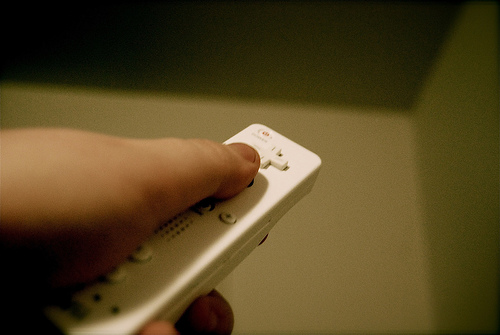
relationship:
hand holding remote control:
[1, 111, 242, 333] [60, 113, 333, 334]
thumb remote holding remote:
[186, 107, 338, 189] [31, 123, 327, 320]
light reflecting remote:
[287, 105, 433, 335] [6, 120, 324, 332]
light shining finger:
[287, 105, 433, 335] [104, 138, 260, 216]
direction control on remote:
[240, 132, 300, 174] [61, 135, 347, 328]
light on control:
[332, 114, 440, 325] [4, 100, 339, 334]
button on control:
[221, 211, 237, 225] [46, 122, 322, 335]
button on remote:
[104, 264, 127, 283] [31, 123, 327, 320]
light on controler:
[85, 283, 114, 319] [44, 122, 321, 335]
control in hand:
[46, 122, 322, 335] [23, 123, 367, 313]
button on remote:
[215, 207, 242, 229] [331, 124, 429, 320]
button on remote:
[259, 145, 288, 170] [26, 85, 342, 327]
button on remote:
[104, 264, 127, 283] [6, 120, 324, 332]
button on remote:
[131, 243, 155, 263] [6, 120, 324, 332]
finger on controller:
[135, 136, 261, 230] [94, 112, 340, 307]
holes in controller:
[144, 206, 199, 240] [15, 108, 325, 333]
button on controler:
[260, 130, 273, 139] [47, 115, 329, 332]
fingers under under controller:
[137, 282, 242, 333] [41, 119, 323, 334]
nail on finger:
[227, 143, 256, 163] [124, 132, 261, 212]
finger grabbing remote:
[135, 137, 260, 239] [51, 121, 322, 333]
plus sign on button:
[223, 212, 230, 220] [218, 209, 236, 224]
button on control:
[254, 125, 278, 141] [52, 122, 336, 334]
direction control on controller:
[259, 145, 289, 170] [41, 119, 323, 334]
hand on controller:
[1, 111, 242, 333] [43, 100, 325, 330]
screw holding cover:
[222, 213, 247, 231] [52, 119, 304, 316]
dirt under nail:
[252, 151, 259, 160] [227, 136, 259, 166]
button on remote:
[259, 145, 288, 170] [24, 99, 351, 331]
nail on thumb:
[227, 143, 256, 163] [101, 99, 274, 233]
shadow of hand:
[1, 214, 127, 335] [0, 129, 234, 246]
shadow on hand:
[4, 214, 126, 323] [1, 111, 242, 333]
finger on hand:
[135, 136, 261, 230] [1, 111, 242, 333]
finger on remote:
[162, 289, 253, 334] [11, 117, 422, 322]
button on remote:
[108, 200, 213, 330] [7, 34, 414, 332]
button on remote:
[257, 144, 288, 173] [6, 43, 367, 330]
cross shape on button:
[206, 113, 391, 208] [257, 148, 288, 173]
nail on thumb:
[226, 141, 258, 164] [139, 135, 261, 230]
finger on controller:
[135, 136, 261, 230] [41, 109, 346, 334]